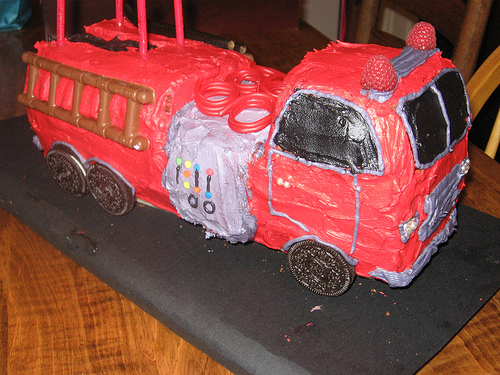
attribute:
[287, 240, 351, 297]
wheel —  Oreo cookie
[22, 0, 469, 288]
frosting — red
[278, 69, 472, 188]
windows — black, silver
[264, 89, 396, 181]
window — black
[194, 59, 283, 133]
licorice — red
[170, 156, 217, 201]
buttons — multicolored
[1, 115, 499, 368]
platform — black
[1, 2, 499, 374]
table — brown, wooden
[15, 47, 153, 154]
frosting ladder — BROWN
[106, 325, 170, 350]
table — brown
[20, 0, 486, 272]
fire truck — red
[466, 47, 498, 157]
chair — wooden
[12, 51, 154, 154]
ladder — brown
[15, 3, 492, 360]
cake — red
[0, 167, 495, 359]
plate — black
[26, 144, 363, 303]
tires — black